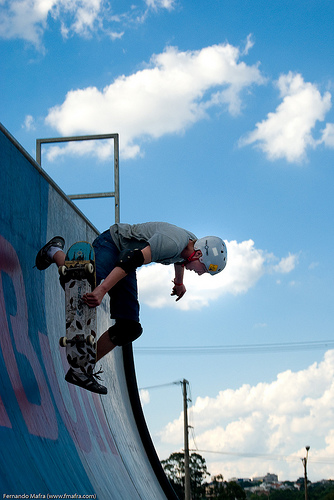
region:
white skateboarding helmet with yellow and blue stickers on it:
[193, 232, 230, 277]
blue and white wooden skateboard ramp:
[0, 118, 184, 498]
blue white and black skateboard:
[58, 238, 99, 374]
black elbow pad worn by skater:
[111, 246, 146, 274]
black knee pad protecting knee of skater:
[106, 316, 145, 347]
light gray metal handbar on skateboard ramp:
[34, 130, 122, 255]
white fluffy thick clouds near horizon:
[152, 341, 332, 477]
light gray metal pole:
[176, 375, 195, 498]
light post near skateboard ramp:
[299, 442, 313, 498]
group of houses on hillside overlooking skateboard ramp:
[191, 468, 316, 498]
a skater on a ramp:
[0, 159, 235, 497]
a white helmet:
[180, 221, 234, 288]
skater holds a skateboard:
[30, 205, 238, 399]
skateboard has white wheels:
[57, 258, 98, 350]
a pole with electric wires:
[168, 367, 205, 498]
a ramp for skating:
[0, 124, 177, 498]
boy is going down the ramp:
[30, 205, 238, 477]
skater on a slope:
[6, 146, 236, 498]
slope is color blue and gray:
[2, 134, 178, 498]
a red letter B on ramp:
[2, 222, 62, 447]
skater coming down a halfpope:
[36, 195, 239, 404]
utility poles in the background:
[180, 377, 315, 498]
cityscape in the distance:
[224, 472, 289, 492]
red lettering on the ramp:
[3, 236, 118, 455]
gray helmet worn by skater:
[194, 234, 227, 274]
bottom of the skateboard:
[63, 243, 98, 374]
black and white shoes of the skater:
[31, 233, 112, 394]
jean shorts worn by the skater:
[92, 232, 143, 321]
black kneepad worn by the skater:
[110, 317, 142, 346]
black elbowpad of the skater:
[119, 246, 143, 273]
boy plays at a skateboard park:
[7, 116, 320, 483]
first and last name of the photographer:
[0, 486, 44, 494]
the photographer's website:
[44, 488, 96, 494]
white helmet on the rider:
[192, 228, 226, 271]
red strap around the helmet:
[180, 244, 197, 263]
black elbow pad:
[113, 244, 142, 270]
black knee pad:
[104, 313, 142, 345]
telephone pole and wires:
[160, 367, 196, 493]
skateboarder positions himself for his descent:
[24, 183, 237, 411]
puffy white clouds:
[212, 353, 330, 442]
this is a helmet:
[175, 208, 262, 286]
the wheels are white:
[76, 261, 103, 292]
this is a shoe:
[39, 235, 52, 267]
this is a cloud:
[101, 185, 256, 336]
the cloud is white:
[223, 355, 269, 431]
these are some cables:
[173, 343, 196, 376]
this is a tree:
[137, 424, 212, 479]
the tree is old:
[174, 446, 205, 479]